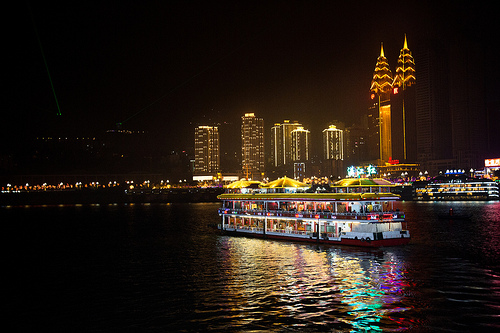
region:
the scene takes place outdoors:
[0, 2, 496, 330]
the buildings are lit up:
[188, 30, 418, 183]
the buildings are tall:
[192, 30, 417, 188]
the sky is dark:
[0, 1, 495, 173]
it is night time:
[1, 10, 498, 331]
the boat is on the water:
[219, 177, 406, 248]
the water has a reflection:
[221, 239, 411, 330]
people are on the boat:
[221, 188, 403, 241]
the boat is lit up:
[220, 176, 403, 252]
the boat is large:
[219, 180, 404, 255]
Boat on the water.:
[154, 117, 441, 325]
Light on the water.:
[208, 208, 316, 303]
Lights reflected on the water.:
[203, 224, 320, 314]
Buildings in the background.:
[138, 72, 483, 189]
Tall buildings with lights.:
[353, 25, 438, 175]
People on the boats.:
[196, 173, 448, 254]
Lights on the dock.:
[41, 164, 201, 218]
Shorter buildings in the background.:
[183, 81, 471, 193]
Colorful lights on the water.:
[296, 212, 428, 331]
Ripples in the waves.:
[206, 244, 393, 320]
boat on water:
[204, 177, 419, 244]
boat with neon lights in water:
[216, 172, 411, 259]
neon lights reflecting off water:
[231, 233, 397, 331]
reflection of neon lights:
[216, 242, 410, 329]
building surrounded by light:
[364, 29, 430, 177]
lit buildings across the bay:
[169, 99, 351, 171]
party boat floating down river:
[214, 179, 424, 252]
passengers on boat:
[208, 172, 418, 247]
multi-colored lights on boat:
[209, 174, 410, 244]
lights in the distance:
[7, 180, 177, 197]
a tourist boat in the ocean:
[209, 184, 414, 243]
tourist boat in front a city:
[172, 40, 487, 251]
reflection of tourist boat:
[220, 217, 410, 327]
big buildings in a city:
[175, 90, 352, 175]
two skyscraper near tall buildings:
[189, 32, 421, 172]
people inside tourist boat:
[222, 196, 392, 211]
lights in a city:
[0, 32, 495, 194]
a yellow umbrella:
[257, 168, 307, 188]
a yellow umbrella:
[216, 172, 262, 188]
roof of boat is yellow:
[208, 190, 401, 212]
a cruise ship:
[216, 175, 406, 241]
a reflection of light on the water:
[222, 240, 369, 317]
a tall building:
[362, 56, 425, 165]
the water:
[45, 213, 159, 301]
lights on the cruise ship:
[225, 174, 383, 242]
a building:
[192, 120, 222, 177]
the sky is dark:
[110, 10, 284, 77]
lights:
[49, 176, 149, 194]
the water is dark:
[45, 231, 167, 304]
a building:
[316, 123, 356, 162]